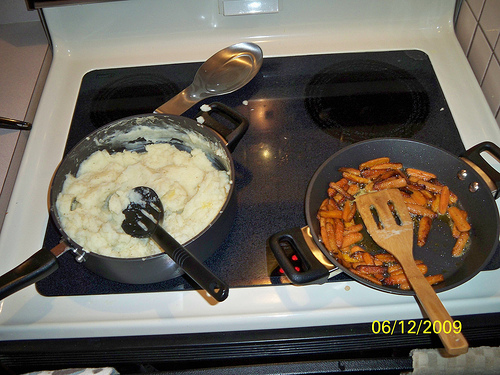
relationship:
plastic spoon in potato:
[126, 234, 242, 314] [93, 163, 165, 212]